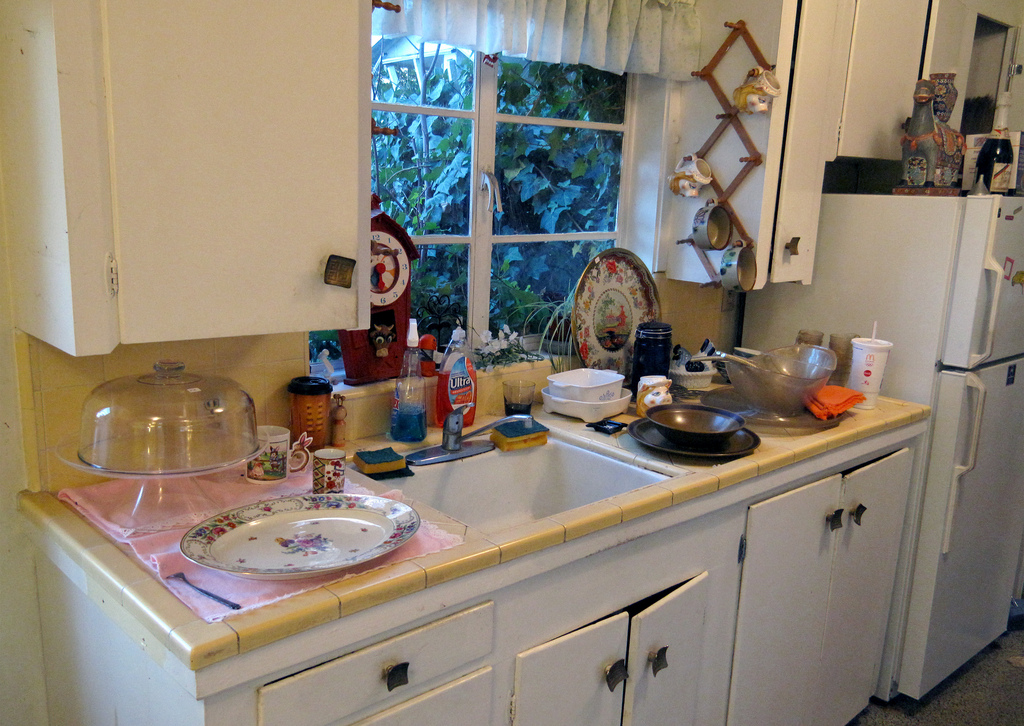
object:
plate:
[182, 490, 425, 579]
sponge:
[351, 446, 406, 474]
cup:
[244, 425, 313, 486]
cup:
[847, 320, 895, 410]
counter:
[20, 344, 935, 681]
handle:
[955, 372, 990, 478]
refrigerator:
[741, 192, 1024, 712]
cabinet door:
[628, 571, 727, 726]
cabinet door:
[511, 611, 626, 726]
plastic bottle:
[389, 317, 430, 443]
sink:
[357, 422, 676, 534]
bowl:
[642, 403, 749, 448]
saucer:
[628, 402, 761, 465]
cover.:
[64, 355, 287, 544]